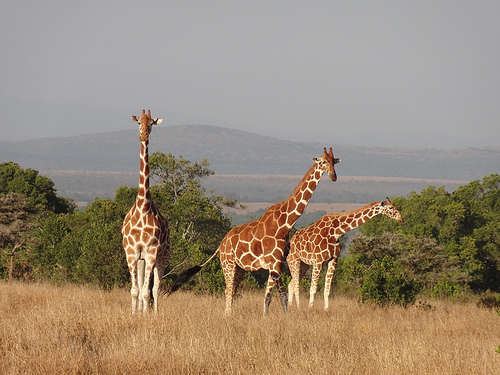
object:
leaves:
[407, 190, 420, 201]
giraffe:
[199, 146, 339, 316]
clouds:
[62, 8, 142, 48]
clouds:
[44, 92, 99, 128]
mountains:
[7, 122, 496, 193]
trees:
[349, 167, 500, 310]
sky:
[2, 1, 499, 136]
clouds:
[228, 54, 316, 95]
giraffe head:
[377, 195, 405, 224]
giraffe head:
[311, 147, 343, 181]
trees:
[0, 161, 74, 282]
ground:
[0, 295, 500, 375]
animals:
[121, 109, 166, 315]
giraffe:
[284, 196, 400, 311]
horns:
[141, 109, 146, 116]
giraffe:
[117, 108, 170, 319]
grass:
[0, 283, 498, 373]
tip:
[162, 266, 200, 293]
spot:
[314, 170, 322, 179]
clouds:
[12, 80, 82, 100]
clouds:
[170, 96, 243, 122]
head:
[130, 108, 163, 141]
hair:
[168, 265, 201, 295]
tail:
[163, 244, 219, 296]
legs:
[321, 261, 333, 312]